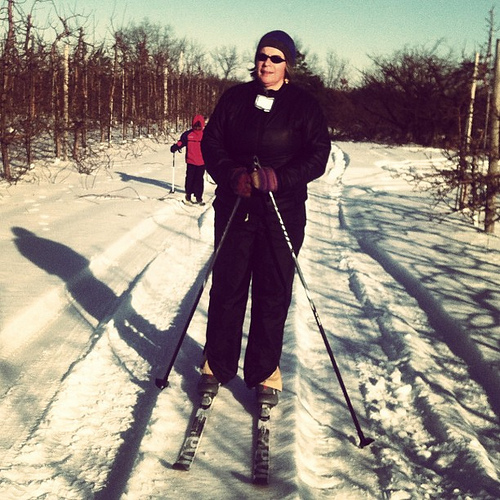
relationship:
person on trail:
[199, 29, 331, 401] [11, 139, 498, 499]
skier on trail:
[168, 109, 217, 204] [11, 139, 498, 499]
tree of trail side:
[457, 47, 472, 214] [329, 132, 496, 497]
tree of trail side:
[482, 35, 499, 232] [329, 132, 496, 497]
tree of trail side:
[52, 25, 72, 161] [329, 132, 496, 497]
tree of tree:
[154, 43, 171, 137] [457, 47, 472, 214]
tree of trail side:
[192, 42, 203, 121] [329, 132, 496, 497]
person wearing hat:
[199, 29, 332, 401] [263, 28, 303, 66]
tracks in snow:
[321, 195, 483, 498] [5, 108, 483, 496]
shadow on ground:
[8, 215, 208, 390] [1, 124, 498, 497]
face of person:
[258, 48, 292, 82] [199, 29, 332, 401]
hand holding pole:
[169, 141, 179, 152] [170, 146, 181, 194]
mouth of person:
[258, 67, 275, 81] [199, 29, 332, 401]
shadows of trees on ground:
[351, 193, 485, 420] [1, 124, 498, 497]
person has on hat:
[199, 29, 331, 401] [262, 31, 314, 55]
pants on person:
[210, 187, 307, 382] [199, 29, 332, 401]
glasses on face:
[256, 52, 285, 66] [253, 45, 283, 85]